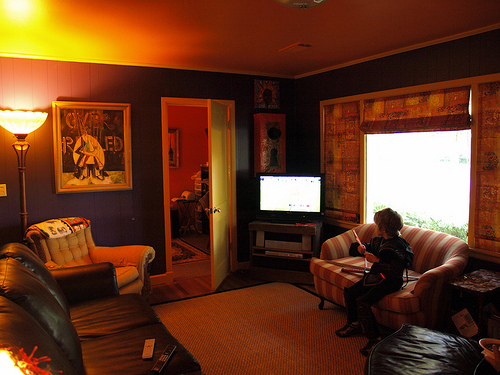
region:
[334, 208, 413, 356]
the boy sitting on the couch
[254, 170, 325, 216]
the tv in the corner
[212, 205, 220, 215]
the knob on the door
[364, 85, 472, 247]
the window behind the boy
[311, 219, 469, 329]
the couch near the window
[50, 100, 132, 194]
the picture on the wall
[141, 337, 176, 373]
the remotes on the couch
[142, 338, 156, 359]
the remote on the couch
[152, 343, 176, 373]
the remote on the couch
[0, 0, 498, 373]
the room filled with furniture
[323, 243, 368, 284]
Big couch up against the wall.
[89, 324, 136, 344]
Big couch up against the wall.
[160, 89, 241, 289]
An open door way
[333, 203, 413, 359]
A kid sitting down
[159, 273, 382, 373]
A white room carpet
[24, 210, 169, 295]
White victorian arm chair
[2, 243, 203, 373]
Black leather sofa couch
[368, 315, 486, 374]
Black leather foot stool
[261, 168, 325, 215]
An lcd tv panel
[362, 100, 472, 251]
A bright open window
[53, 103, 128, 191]
A picture hanging on wall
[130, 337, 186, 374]
Remote controls sitting on couch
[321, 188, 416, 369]
the boy is sitting on the chair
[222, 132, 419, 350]
the boy is watching the TV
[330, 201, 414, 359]
Child sitting on the couch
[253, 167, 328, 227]
TV sitting in the corner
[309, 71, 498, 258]
Decorative curtains around the window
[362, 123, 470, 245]
Open window area behind the boy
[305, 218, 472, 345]
Striped couch with child on it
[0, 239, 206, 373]
Brown leather couch on the left side of the room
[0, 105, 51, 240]
Floor lamp that is turned on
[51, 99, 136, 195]
Framed picture on the wood wall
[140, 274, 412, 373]
Area rug in front of the couch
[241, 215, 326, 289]
Wooden tv stand in the corner